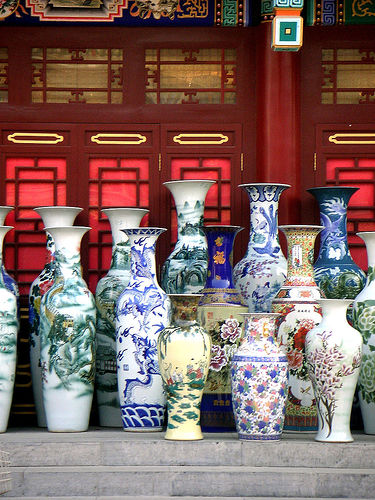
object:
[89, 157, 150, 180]
section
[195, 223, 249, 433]
blue vase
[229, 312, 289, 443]
vessel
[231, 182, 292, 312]
vessel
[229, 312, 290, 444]
vase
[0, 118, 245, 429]
door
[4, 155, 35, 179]
red section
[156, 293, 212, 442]
vase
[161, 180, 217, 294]
vases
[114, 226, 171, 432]
vase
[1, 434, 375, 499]
stand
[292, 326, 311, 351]
flower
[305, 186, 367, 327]
vase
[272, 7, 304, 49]
orange decorations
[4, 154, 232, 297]
windows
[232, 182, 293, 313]
vase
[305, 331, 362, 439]
flowers decorations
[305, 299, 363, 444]
vase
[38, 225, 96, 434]
vases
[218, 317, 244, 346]
flower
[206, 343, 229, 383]
flower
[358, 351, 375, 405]
flower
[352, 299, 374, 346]
flower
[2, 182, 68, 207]
section/door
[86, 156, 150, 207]
section/door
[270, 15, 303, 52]
socket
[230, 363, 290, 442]
flowers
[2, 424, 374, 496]
surface